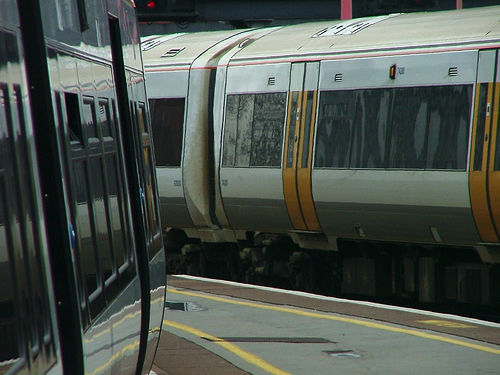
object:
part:
[389, 153, 416, 169]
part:
[414, 141, 430, 164]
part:
[346, 157, 366, 168]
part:
[170, 122, 179, 145]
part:
[260, 155, 281, 172]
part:
[154, 155, 180, 167]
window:
[156, 105, 183, 168]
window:
[140, 143, 167, 235]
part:
[113, 220, 131, 243]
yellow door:
[291, 78, 311, 156]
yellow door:
[467, 50, 499, 218]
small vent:
[263, 75, 277, 85]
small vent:
[341, 99, 354, 104]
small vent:
[448, 67, 458, 78]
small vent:
[166, 100, 178, 112]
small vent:
[172, 176, 181, 187]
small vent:
[218, 177, 228, 189]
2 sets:
[281, 99, 499, 244]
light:
[388, 61, 396, 79]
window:
[285, 88, 311, 167]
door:
[279, 59, 319, 235]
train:
[141, 3, 482, 310]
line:
[165, 286, 474, 354]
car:
[209, 1, 499, 312]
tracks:
[166, 246, 479, 336]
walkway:
[153, 269, 484, 369]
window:
[220, 87, 284, 169]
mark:
[309, 13, 396, 38]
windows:
[11, 79, 53, 338]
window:
[62, 88, 88, 148]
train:
[2, 1, 168, 367]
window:
[77, 96, 99, 141]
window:
[95, 95, 114, 138]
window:
[134, 100, 149, 140]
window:
[313, 87, 356, 174]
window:
[351, 87, 388, 167]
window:
[383, 80, 429, 175]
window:
[423, 82, 471, 170]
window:
[251, 90, 284, 169]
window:
[221, 90, 250, 164]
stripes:
[227, 33, 481, 63]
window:
[222, 95, 286, 169]